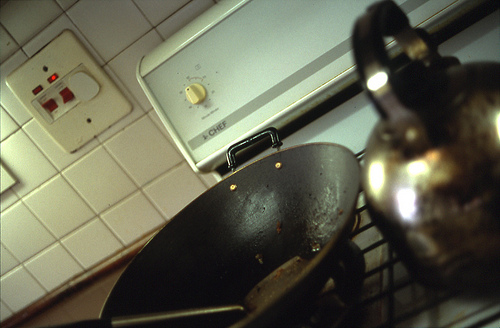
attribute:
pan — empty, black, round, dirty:
[99, 127, 362, 328]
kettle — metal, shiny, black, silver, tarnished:
[348, 0, 499, 296]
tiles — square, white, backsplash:
[1, 0, 220, 327]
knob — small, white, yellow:
[182, 82, 206, 105]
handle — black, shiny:
[225, 126, 284, 168]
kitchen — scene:
[1, 0, 499, 327]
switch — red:
[41, 97, 59, 114]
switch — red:
[59, 84, 76, 104]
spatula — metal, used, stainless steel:
[48, 255, 309, 327]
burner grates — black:
[345, 147, 450, 326]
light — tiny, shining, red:
[49, 74, 57, 84]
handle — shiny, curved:
[351, 0, 430, 119]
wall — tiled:
[1, 0, 227, 327]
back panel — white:
[135, 1, 499, 177]